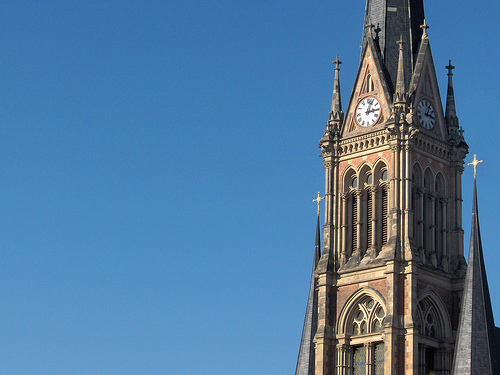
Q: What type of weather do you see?
A: It is cloudless.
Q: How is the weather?
A: It is cloudless.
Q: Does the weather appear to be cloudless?
A: Yes, it is cloudless.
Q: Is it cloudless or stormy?
A: It is cloudless.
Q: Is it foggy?
A: No, it is cloudless.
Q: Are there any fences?
A: No, there are no fences.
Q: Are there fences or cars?
A: No, there are no fences or cars.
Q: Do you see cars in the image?
A: No, there are no cars.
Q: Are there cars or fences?
A: No, there are no cars or fences.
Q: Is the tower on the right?
A: Yes, the tower is on the right of the image.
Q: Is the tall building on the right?
A: Yes, the tower is on the right of the image.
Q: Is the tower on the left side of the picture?
A: No, the tower is on the right of the image.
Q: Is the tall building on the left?
A: No, the tower is on the right of the image.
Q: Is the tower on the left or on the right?
A: The tower is on the right of the image.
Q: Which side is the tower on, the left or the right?
A: The tower is on the right of the image.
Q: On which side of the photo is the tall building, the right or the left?
A: The tower is on the right of the image.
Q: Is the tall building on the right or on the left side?
A: The tower is on the right of the image.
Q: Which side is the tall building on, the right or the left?
A: The tower is on the right of the image.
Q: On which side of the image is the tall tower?
A: The tower is on the right of the image.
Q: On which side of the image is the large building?
A: The tower is on the right of the image.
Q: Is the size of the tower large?
A: Yes, the tower is large.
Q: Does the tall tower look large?
A: Yes, the tower is large.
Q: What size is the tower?
A: The tower is large.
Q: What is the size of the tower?
A: The tower is large.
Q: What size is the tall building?
A: The tower is large.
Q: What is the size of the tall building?
A: The tower is large.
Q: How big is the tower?
A: The tower is large.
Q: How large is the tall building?
A: The tower is large.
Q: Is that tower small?
A: No, the tower is large.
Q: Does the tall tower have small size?
A: No, the tower is large.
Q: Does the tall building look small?
A: No, the tower is large.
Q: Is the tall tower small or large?
A: The tower is large.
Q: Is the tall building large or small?
A: The tower is large.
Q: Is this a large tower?
A: Yes, this is a large tower.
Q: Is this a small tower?
A: No, this is a large tower.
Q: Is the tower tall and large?
A: Yes, the tower is tall and large.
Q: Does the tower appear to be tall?
A: Yes, the tower is tall.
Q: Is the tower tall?
A: Yes, the tower is tall.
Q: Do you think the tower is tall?
A: Yes, the tower is tall.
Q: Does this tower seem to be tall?
A: Yes, the tower is tall.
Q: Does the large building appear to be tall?
A: Yes, the tower is tall.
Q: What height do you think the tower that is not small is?
A: The tower is tall.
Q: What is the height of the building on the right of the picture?
A: The tower is tall.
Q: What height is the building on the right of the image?
A: The tower is tall.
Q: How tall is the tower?
A: The tower is tall.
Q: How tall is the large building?
A: The tower is tall.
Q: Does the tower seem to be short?
A: No, the tower is tall.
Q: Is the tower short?
A: No, the tower is tall.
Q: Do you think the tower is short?
A: No, the tower is tall.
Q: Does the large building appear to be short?
A: No, the tower is tall.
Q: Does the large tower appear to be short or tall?
A: The tower is tall.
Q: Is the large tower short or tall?
A: The tower is tall.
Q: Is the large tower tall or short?
A: The tower is tall.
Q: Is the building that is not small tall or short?
A: The tower is tall.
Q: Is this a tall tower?
A: Yes, this is a tall tower.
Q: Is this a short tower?
A: No, this is a tall tower.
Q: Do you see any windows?
A: Yes, there are windows.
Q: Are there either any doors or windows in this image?
A: Yes, there are windows.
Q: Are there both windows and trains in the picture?
A: No, there are windows but no trains.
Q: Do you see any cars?
A: No, there are no cars.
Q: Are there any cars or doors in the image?
A: No, there are no cars or doors.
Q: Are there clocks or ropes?
A: Yes, there is a clock.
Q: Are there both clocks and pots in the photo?
A: No, there is a clock but no pots.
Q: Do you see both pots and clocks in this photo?
A: No, there is a clock but no pots.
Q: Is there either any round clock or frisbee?
A: Yes, there is a round clock.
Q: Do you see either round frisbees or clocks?
A: Yes, there is a round clock.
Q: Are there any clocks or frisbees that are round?
A: Yes, the clock is round.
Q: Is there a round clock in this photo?
A: Yes, there is a round clock.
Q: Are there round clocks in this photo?
A: Yes, there is a round clock.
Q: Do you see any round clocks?
A: Yes, there is a round clock.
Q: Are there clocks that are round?
A: Yes, there is a clock that is round.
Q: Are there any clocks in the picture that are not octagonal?
A: Yes, there is an round clock.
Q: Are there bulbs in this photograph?
A: No, there are no bulbs.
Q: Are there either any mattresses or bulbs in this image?
A: No, there are no bulbs or mattresses.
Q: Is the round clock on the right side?
A: Yes, the clock is on the right of the image.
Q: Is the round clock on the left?
A: No, the clock is on the right of the image.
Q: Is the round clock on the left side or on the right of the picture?
A: The clock is on the right of the image.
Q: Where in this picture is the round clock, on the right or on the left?
A: The clock is on the right of the image.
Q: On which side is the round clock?
A: The clock is on the right of the image.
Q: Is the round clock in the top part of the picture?
A: Yes, the clock is in the top of the image.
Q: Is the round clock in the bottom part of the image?
A: No, the clock is in the top of the image.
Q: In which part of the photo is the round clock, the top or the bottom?
A: The clock is in the top of the image.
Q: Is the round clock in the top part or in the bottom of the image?
A: The clock is in the top of the image.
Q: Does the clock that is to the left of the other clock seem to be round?
A: Yes, the clock is round.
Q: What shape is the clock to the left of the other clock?
A: The clock is round.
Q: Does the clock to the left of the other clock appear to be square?
A: No, the clock is round.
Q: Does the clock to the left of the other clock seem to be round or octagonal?
A: The clock is round.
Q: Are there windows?
A: Yes, there is a window.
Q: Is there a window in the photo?
A: Yes, there is a window.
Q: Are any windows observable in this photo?
A: Yes, there is a window.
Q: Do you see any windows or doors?
A: Yes, there is a window.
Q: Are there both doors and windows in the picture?
A: No, there is a window but no doors.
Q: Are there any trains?
A: No, there are no trains.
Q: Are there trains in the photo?
A: No, there are no trains.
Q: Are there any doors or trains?
A: No, there are no trains or doors.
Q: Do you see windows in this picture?
A: Yes, there is a window.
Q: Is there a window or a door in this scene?
A: Yes, there is a window.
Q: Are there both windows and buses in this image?
A: No, there is a window but no buses.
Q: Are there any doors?
A: No, there are no doors.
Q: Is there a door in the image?
A: No, there are no doors.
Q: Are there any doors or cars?
A: No, there are no doors or cars.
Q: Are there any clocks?
A: Yes, there is a clock.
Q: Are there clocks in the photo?
A: Yes, there is a clock.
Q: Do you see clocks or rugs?
A: Yes, there is a clock.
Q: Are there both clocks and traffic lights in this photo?
A: No, there is a clock but no traffic lights.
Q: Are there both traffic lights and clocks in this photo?
A: No, there is a clock but no traffic lights.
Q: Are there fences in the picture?
A: No, there are no fences.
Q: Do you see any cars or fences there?
A: No, there are no fences or cars.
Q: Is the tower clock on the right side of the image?
A: Yes, the clock is on the right of the image.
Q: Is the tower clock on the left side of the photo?
A: No, the clock is on the right of the image.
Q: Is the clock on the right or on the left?
A: The clock is on the right of the image.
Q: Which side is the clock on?
A: The clock is on the right of the image.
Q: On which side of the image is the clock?
A: The clock is on the right of the image.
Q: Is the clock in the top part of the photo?
A: Yes, the clock is in the top of the image.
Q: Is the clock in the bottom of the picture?
A: No, the clock is in the top of the image.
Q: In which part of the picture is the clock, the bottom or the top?
A: The clock is in the top of the image.